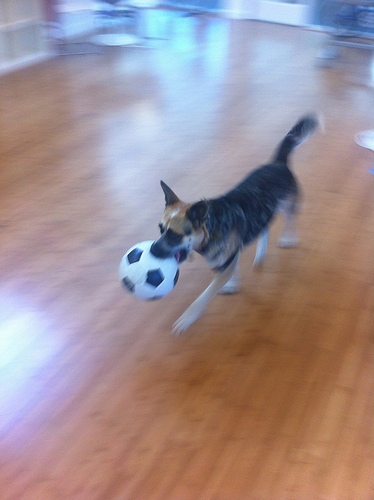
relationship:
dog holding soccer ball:
[163, 117, 324, 312] [118, 242, 184, 303]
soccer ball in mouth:
[118, 242, 184, 303] [148, 241, 197, 268]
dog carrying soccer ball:
[163, 117, 324, 312] [118, 242, 184, 303]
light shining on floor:
[59, 7, 233, 46] [30, 52, 358, 415]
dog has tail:
[163, 117, 324, 312] [275, 108, 324, 161]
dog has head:
[163, 117, 324, 312] [151, 184, 210, 270]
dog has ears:
[163, 117, 324, 312] [157, 178, 215, 223]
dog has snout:
[163, 117, 324, 312] [151, 244, 170, 254]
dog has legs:
[163, 117, 324, 312] [251, 218, 313, 266]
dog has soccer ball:
[163, 117, 324, 312] [118, 238, 181, 305]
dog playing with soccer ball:
[163, 117, 324, 312] [118, 242, 184, 303]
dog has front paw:
[163, 117, 324, 312] [162, 318, 194, 339]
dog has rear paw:
[163, 117, 324, 312] [275, 231, 306, 253]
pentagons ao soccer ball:
[127, 248, 165, 289] [118, 238, 181, 305]